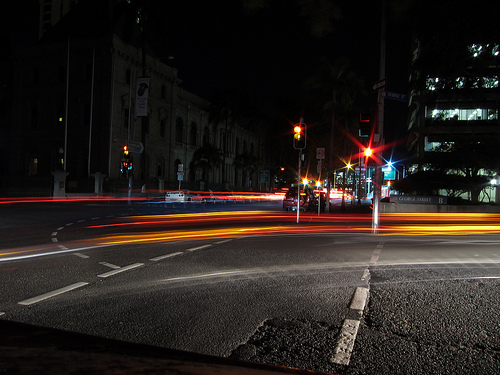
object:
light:
[291, 125, 304, 136]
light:
[360, 142, 376, 161]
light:
[123, 145, 128, 152]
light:
[344, 162, 354, 169]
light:
[387, 160, 395, 167]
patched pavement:
[228, 264, 499, 374]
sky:
[82, 0, 447, 124]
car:
[282, 182, 315, 211]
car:
[165, 191, 194, 204]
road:
[3, 188, 495, 373]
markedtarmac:
[260, 235, 398, 373]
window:
[425, 140, 451, 151]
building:
[373, 34, 498, 228]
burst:
[376, 150, 405, 180]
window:
[429, 108, 446, 121]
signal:
[121, 160, 132, 170]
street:
[2, 200, 496, 372]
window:
[444, 106, 462, 121]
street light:
[315, 180, 324, 188]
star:
[347, 128, 395, 170]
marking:
[96, 258, 146, 280]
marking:
[148, 248, 185, 261]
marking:
[17, 277, 90, 305]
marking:
[56, 242, 89, 259]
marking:
[184, 240, 211, 253]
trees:
[187, 142, 265, 187]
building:
[30, 35, 277, 196]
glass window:
[430, 106, 442, 119]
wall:
[113, 116, 129, 152]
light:
[446, 106, 460, 121]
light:
[464, 107, 480, 120]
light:
[426, 106, 448, 121]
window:
[481, 107, 498, 118]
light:
[74, 225, 499, 242]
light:
[122, 208, 497, 220]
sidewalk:
[315, 196, 498, 231]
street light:
[300, 176, 310, 185]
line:
[347, 238, 390, 373]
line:
[54, 207, 179, 271]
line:
[0, 235, 239, 313]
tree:
[391, 119, 466, 197]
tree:
[450, 112, 499, 201]